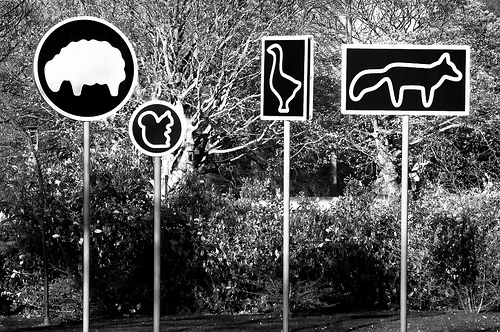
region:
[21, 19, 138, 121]
The sign is round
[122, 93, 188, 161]
The sign is round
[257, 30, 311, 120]
The sign is rectangle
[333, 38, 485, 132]
The sign is square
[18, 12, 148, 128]
The sign is black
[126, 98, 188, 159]
The sign is black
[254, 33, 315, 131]
The sign is black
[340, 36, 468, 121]
The sign is black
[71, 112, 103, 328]
The pole is gray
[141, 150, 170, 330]
The pole is gray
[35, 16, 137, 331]
a sign featuring a sheep image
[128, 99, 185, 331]
a sign with a squirrel on it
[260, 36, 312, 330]
a sign featuring a goose image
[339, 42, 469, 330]
a sign featuring a fox image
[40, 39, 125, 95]
a white sheep image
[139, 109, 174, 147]
picture of a squirrel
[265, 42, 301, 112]
a picture of a goose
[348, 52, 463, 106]
a picture of a fox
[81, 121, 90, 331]
a grey metal pole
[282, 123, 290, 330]
a white metal pole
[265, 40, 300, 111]
A symbol for a goose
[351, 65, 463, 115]
A symbol for a fox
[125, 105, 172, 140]
A symbol for a bird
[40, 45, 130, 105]
A symbol for a sheep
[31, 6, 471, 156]
Four animal signs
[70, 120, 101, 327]
A pole holding up a sheep sign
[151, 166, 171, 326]
A pole holding up a bird sign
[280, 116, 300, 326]
A pole holding up a goose sign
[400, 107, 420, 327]
A pole holding up a fox sign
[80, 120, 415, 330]
Four poles holding up signs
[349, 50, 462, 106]
Black and white fox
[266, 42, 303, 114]
Black and white duck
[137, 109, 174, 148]
Black and white squirrel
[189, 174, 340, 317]
Black and white bush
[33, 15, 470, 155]
Black and white signs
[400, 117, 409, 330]
Black and white sign pole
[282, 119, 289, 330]
Black and white sign poll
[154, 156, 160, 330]
Black and white sign pole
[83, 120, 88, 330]
Black and white sign pole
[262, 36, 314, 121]
Black and white duck sign